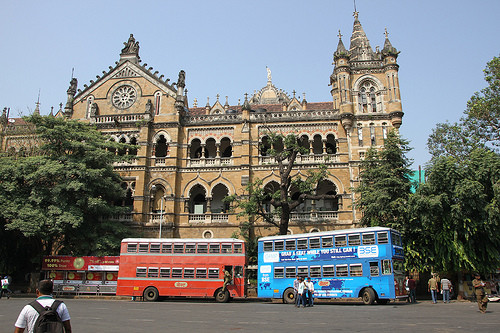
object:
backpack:
[27, 296, 74, 333]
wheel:
[280, 286, 299, 304]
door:
[221, 264, 234, 294]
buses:
[37, 220, 414, 310]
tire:
[359, 285, 376, 306]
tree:
[0, 108, 132, 293]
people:
[293, 275, 305, 310]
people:
[303, 275, 316, 307]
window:
[124, 244, 139, 253]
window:
[231, 243, 242, 254]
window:
[146, 243, 161, 254]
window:
[182, 243, 197, 254]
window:
[208, 242, 220, 253]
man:
[14, 279, 73, 332]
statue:
[263, 65, 273, 82]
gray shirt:
[439, 277, 452, 291]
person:
[468, 270, 488, 315]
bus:
[255, 223, 407, 305]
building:
[63, 0, 406, 296]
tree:
[410, 54, 499, 300]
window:
[152, 134, 170, 167]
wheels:
[140, 285, 158, 302]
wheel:
[211, 286, 229, 302]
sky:
[0, 0, 499, 171]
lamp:
[160, 192, 175, 200]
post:
[156, 198, 162, 241]